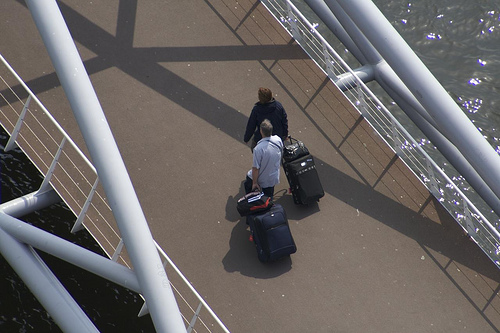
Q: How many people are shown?
A: 2.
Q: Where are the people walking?
A: Bridge.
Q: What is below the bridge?
A: Water.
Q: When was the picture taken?
A: Daytime.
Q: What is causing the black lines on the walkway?
A: Shadows.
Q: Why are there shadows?
A: Sunny day.